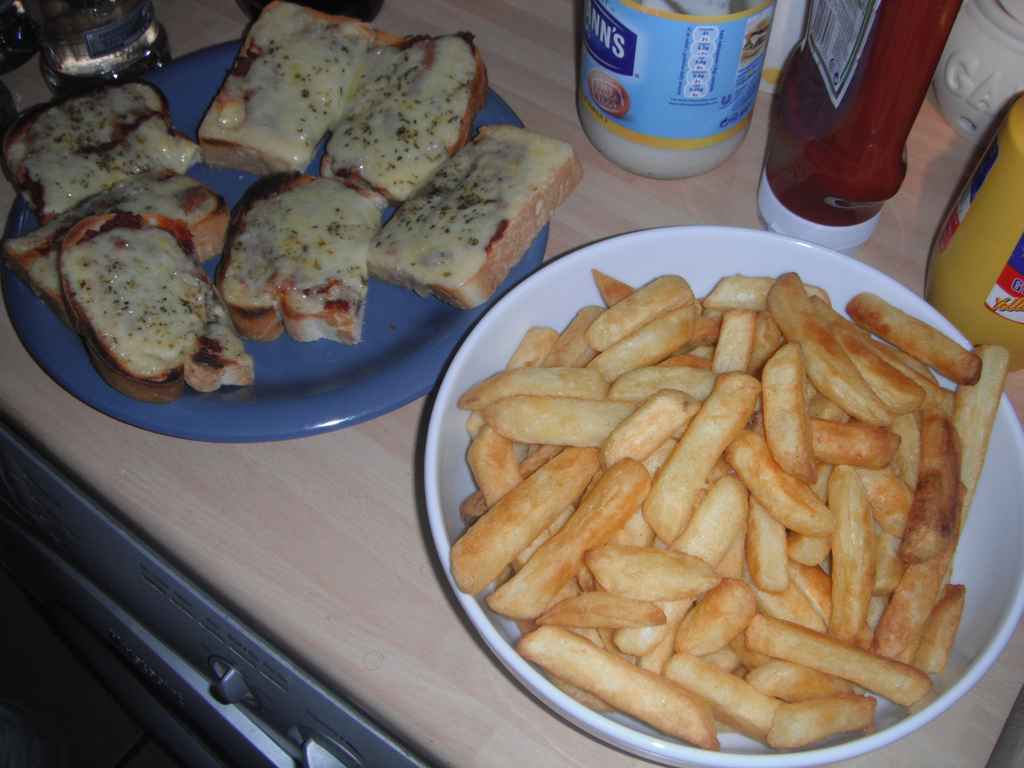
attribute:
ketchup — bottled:
[771, 0, 940, 250]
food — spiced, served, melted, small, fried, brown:
[58, 58, 968, 629]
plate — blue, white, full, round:
[68, 72, 928, 568]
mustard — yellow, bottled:
[929, 61, 1022, 345]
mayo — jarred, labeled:
[571, 0, 768, 207]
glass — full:
[27, 0, 189, 87]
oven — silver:
[22, 537, 414, 766]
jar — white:
[929, 0, 1011, 168]